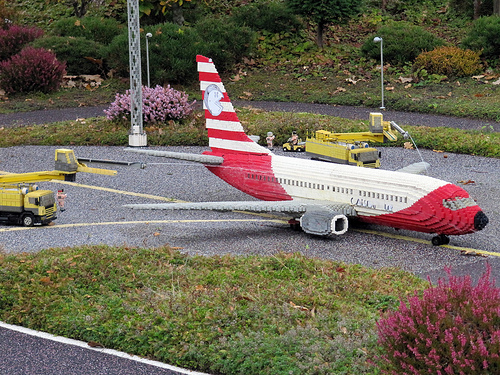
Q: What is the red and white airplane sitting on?
A: Pavement.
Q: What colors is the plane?
A: Red and white.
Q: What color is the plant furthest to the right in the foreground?
A: Purple.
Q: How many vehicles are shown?
A: Four.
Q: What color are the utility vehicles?
A: Yellow.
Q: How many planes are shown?
A: One.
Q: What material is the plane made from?
A: Legos.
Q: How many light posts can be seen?
A: Two.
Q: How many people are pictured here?
A: Three.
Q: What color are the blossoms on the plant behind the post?
A: Pink.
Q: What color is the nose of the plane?
A: Black.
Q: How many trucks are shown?
A: 2.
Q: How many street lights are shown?
A: 2.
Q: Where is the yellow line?
A: Under plane.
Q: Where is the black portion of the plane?
A: Nose.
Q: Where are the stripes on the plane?
A: Tail.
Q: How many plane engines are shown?
A: 1.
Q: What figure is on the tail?
A: Pac Man.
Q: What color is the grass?
A: Green.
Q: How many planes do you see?
A: 1.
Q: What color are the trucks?
A: Yellow.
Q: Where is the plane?
A: On the ground.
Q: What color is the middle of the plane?
A: White.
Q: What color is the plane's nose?
A: Black.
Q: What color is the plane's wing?
A: Gray.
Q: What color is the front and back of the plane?
A: Red.